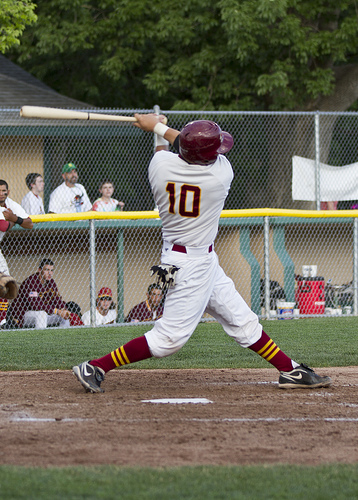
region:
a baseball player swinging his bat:
[20, 106, 328, 392]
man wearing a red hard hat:
[181, 120, 233, 162]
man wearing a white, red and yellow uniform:
[90, 149, 290, 373]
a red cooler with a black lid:
[296, 274, 324, 315]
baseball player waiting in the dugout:
[0, 258, 159, 327]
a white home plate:
[140, 395, 209, 405]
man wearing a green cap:
[58, 160, 78, 173]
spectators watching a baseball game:
[0, 162, 121, 228]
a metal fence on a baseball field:
[1, 107, 356, 331]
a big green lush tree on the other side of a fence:
[1, 2, 356, 209]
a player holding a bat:
[21, 102, 330, 392]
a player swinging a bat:
[18, 104, 334, 390]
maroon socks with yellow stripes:
[90, 337, 292, 375]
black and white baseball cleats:
[74, 358, 330, 390]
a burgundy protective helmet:
[179, 119, 234, 162]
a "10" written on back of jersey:
[164, 181, 201, 217]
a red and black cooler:
[296, 275, 327, 314]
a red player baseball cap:
[97, 286, 112, 300]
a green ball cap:
[61, 162, 77, 173]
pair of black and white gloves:
[149, 264, 179, 286]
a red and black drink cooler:
[296, 275, 328, 316]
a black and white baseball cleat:
[277, 362, 332, 390]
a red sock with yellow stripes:
[92, 331, 150, 373]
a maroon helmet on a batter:
[174, 118, 237, 162]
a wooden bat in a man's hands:
[17, 103, 172, 127]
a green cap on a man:
[60, 160, 80, 174]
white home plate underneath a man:
[135, 391, 214, 410]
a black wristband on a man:
[15, 216, 24, 226]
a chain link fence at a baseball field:
[0, 110, 356, 325]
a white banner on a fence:
[285, 150, 357, 199]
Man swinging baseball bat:
[14, 98, 337, 391]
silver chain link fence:
[4, 107, 350, 303]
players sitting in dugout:
[1, 254, 171, 320]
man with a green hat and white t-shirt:
[49, 160, 89, 211]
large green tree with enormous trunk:
[107, 0, 351, 207]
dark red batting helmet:
[179, 119, 231, 160]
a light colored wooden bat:
[16, 103, 168, 129]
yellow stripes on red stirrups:
[109, 348, 131, 368]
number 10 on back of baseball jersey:
[159, 176, 203, 224]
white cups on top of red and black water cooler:
[296, 264, 325, 313]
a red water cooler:
[296, 272, 329, 319]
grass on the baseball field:
[17, 467, 311, 497]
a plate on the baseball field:
[133, 390, 216, 413]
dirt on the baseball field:
[22, 380, 356, 457]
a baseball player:
[68, 108, 315, 388]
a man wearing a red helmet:
[166, 119, 242, 169]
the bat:
[13, 97, 132, 131]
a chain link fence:
[9, 107, 355, 342]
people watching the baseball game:
[6, 169, 172, 324]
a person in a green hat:
[52, 163, 89, 208]